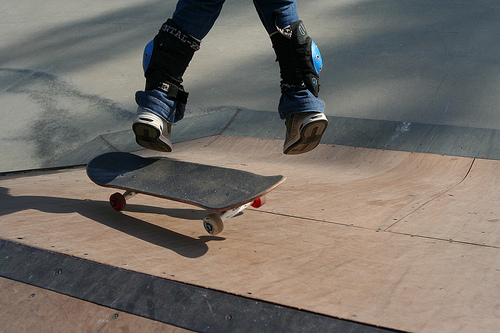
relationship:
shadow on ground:
[6, 180, 210, 267] [3, 227, 235, 301]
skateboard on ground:
[83, 148, 287, 236] [2, 133, 498, 331]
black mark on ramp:
[381, 262, 421, 316] [7, 118, 498, 330]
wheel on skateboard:
[189, 209, 246, 248] [83, 148, 287, 236]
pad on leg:
[265, 16, 335, 100] [250, 0, 330, 120]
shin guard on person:
[268, 15, 327, 98] [123, 0, 335, 158]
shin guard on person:
[133, 27, 210, 109] [123, 0, 335, 158]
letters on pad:
[160, 22, 201, 50] [132, 29, 209, 95]